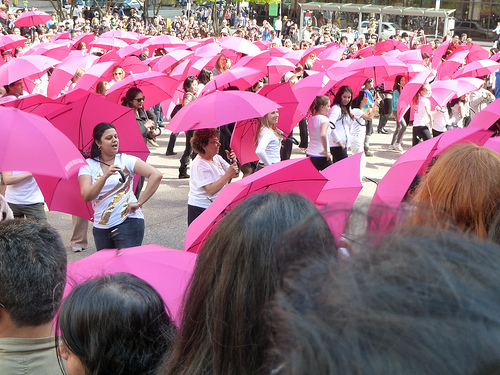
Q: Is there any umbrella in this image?
A: Yes, there is an umbrella.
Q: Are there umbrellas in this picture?
A: Yes, there is an umbrella.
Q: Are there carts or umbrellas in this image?
A: Yes, there is an umbrella.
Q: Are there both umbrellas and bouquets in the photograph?
A: No, there is an umbrella but no bouquets.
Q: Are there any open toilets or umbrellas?
A: Yes, there is an open umbrella.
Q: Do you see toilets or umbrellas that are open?
A: Yes, the umbrella is open.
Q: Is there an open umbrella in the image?
A: Yes, there is an open umbrella.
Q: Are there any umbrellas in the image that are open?
A: Yes, there is an open umbrella.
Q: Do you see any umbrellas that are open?
A: Yes, there is an umbrella that is open.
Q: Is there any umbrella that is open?
A: Yes, there is an umbrella that is open.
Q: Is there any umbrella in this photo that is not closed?
A: Yes, there is a open umbrella.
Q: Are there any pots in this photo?
A: No, there are no pots.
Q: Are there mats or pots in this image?
A: No, there are no pots or mats.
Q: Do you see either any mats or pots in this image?
A: No, there are no pots or mats.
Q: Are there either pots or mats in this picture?
A: No, there are no pots or mats.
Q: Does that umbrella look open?
A: Yes, the umbrella is open.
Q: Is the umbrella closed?
A: No, the umbrella is open.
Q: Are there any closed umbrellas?
A: No, there is an umbrella but it is open.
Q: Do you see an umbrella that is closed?
A: No, there is an umbrella but it is open.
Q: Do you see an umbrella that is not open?
A: No, there is an umbrella but it is open.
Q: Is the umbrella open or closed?
A: The umbrella is open.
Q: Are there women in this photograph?
A: Yes, there is a woman.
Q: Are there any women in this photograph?
A: Yes, there is a woman.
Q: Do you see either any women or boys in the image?
A: Yes, there is a woman.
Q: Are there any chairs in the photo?
A: No, there are no chairs.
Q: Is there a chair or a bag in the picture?
A: No, there are no chairs or bags.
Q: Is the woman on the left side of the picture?
A: Yes, the woman is on the left of the image.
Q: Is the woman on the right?
A: No, the woman is on the left of the image.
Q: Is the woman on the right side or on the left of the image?
A: The woman is on the left of the image.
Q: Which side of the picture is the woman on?
A: The woman is on the left of the image.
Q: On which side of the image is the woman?
A: The woman is on the left of the image.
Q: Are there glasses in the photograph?
A: No, there are no glasses.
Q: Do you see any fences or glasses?
A: No, there are no glasses or fences.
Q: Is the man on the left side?
A: Yes, the man is on the left of the image.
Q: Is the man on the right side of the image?
A: No, the man is on the left of the image.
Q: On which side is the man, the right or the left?
A: The man is on the left of the image.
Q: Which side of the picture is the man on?
A: The man is on the left of the image.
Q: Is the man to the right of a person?
A: No, the man is to the left of a person.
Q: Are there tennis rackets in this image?
A: No, there are no tennis rackets.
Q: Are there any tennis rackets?
A: No, there are no tennis rackets.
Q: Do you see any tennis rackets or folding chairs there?
A: No, there are no tennis rackets or folding chairs.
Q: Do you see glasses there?
A: No, there are no glasses.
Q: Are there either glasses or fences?
A: No, there are no glasses or fences.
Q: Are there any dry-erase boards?
A: No, there are no dry-erase boards.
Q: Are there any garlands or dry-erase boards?
A: No, there are no dry-erase boards or garlands.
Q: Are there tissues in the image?
A: No, there are no tissues.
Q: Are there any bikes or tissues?
A: No, there are no tissues or bikes.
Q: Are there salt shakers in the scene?
A: No, there are no salt shakers.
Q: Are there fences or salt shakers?
A: No, there are no salt shakers or fences.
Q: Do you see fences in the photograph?
A: No, there are no fences.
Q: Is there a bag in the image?
A: No, there are no bags.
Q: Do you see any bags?
A: No, there are no bags.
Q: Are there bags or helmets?
A: No, there are no bags or helmets.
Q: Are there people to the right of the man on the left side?
A: Yes, there is a person to the right of the man.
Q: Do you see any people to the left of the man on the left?
A: No, the person is to the right of the man.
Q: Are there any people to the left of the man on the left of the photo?
A: No, the person is to the right of the man.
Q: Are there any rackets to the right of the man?
A: No, there is a person to the right of the man.